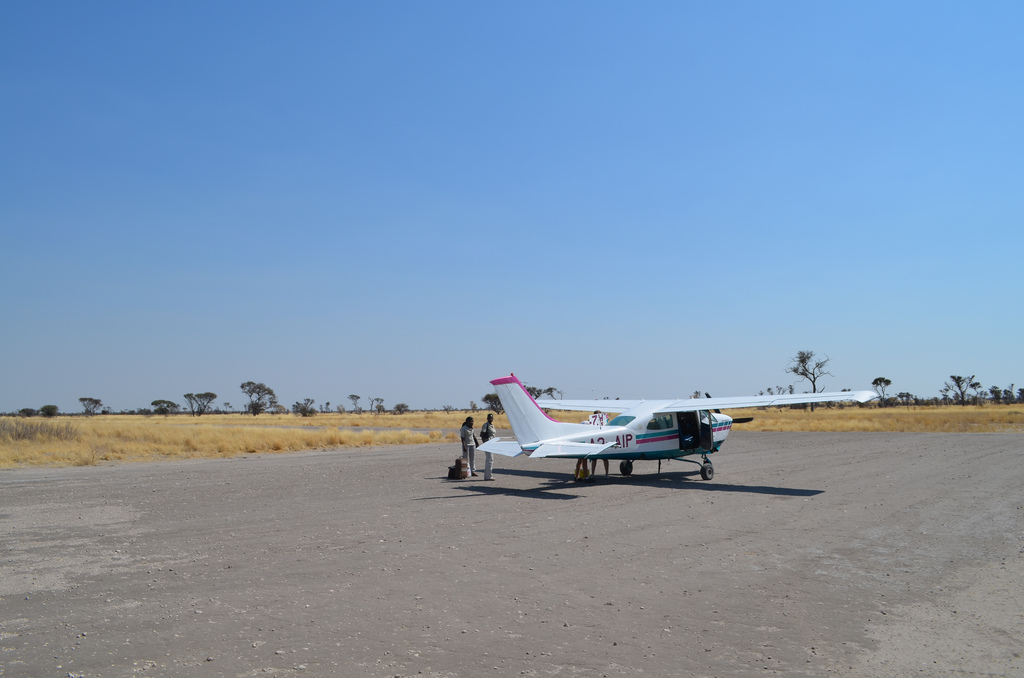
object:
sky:
[0, 0, 1024, 415]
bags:
[447, 459, 467, 480]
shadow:
[411, 468, 825, 500]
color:
[488, 372, 562, 422]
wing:
[534, 399, 643, 413]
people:
[479, 413, 496, 481]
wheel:
[699, 463, 715, 481]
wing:
[654, 390, 881, 413]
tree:
[944, 374, 976, 406]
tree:
[101, 406, 110, 415]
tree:
[871, 376, 891, 408]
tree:
[542, 386, 570, 411]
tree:
[480, 393, 505, 415]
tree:
[895, 392, 911, 407]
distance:
[0, 350, 1024, 472]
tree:
[391, 403, 408, 416]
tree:
[367, 396, 375, 415]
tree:
[336, 403, 347, 414]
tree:
[291, 398, 319, 417]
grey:
[0, 423, 1024, 678]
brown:
[161, 422, 219, 449]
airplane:
[476, 373, 879, 480]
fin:
[476, 373, 637, 447]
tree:
[79, 397, 106, 417]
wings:
[532, 391, 882, 414]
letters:
[591, 434, 634, 450]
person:
[458, 416, 478, 476]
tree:
[38, 405, 58, 419]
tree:
[151, 399, 181, 414]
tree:
[183, 391, 200, 417]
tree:
[187, 391, 215, 417]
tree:
[239, 380, 277, 417]